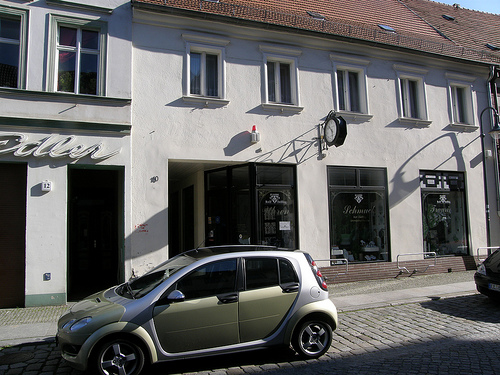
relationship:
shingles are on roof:
[390, 5, 485, 37] [153, 1, 498, 62]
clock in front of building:
[320, 109, 349, 151] [0, 0, 498, 308]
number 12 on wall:
[38, 175, 56, 196] [18, 125, 70, 315]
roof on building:
[132, 0, 498, 66] [0, 0, 498, 308]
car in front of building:
[474, 239, 499, 299] [6, 1, 488, 276]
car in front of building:
[55, 243, 340, 373] [6, 1, 488, 276]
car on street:
[55, 243, 341, 372] [323, 298, 483, 361]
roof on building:
[132, 0, 498, 66] [104, 3, 498, 245]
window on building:
[327, 162, 390, 264] [104, 3, 498, 245]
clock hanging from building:
[320, 109, 349, 149] [192, 61, 476, 227]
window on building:
[420, 169, 470, 258] [0, 0, 498, 308]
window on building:
[319, 154, 396, 265] [150, 80, 488, 262]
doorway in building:
[195, 168, 272, 256] [6, 1, 488, 276]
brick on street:
[9, 274, 497, 362] [331, 292, 489, 358]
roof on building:
[132, 0, 498, 66] [48, 2, 488, 234]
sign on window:
[277, 217, 292, 230] [321, 160, 398, 264]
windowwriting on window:
[343, 203, 377, 215] [261, 178, 302, 250]